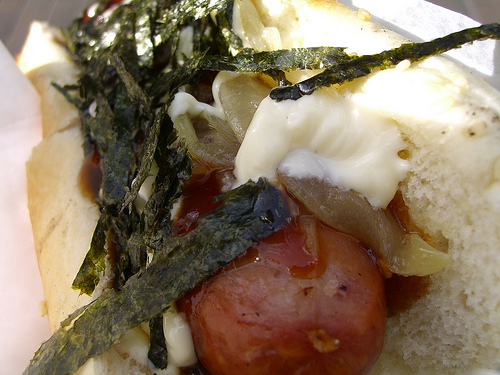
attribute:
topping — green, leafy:
[21, 0, 500, 374]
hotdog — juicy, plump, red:
[188, 198, 388, 375]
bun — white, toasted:
[15, 1, 500, 374]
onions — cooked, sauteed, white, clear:
[169, 73, 449, 277]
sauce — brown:
[78, 147, 324, 318]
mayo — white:
[233, 89, 409, 211]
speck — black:
[340, 283, 348, 292]